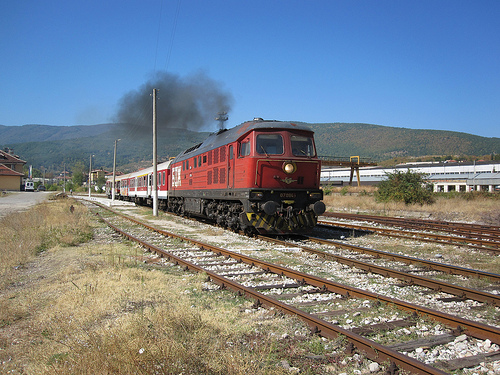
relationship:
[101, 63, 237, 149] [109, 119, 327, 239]
black smoke emerging from train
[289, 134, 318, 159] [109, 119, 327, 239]
window of train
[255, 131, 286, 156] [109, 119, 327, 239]
window of train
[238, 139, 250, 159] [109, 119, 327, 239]
window of train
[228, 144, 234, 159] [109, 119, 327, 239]
window of train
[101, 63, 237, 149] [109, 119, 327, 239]
black smoke from train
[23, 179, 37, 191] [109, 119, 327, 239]
van behind train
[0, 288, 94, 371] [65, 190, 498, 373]
dead grass along side of railroad track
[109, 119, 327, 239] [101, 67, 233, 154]
train puffing smoke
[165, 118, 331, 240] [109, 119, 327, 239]
red car leading train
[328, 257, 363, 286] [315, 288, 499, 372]
stones between railroad tracks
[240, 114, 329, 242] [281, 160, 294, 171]
front train with headlight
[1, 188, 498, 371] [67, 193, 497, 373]
dead grass beside tracks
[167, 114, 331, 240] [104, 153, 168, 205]
red car leads cars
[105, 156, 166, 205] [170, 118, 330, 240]
cars behind engine